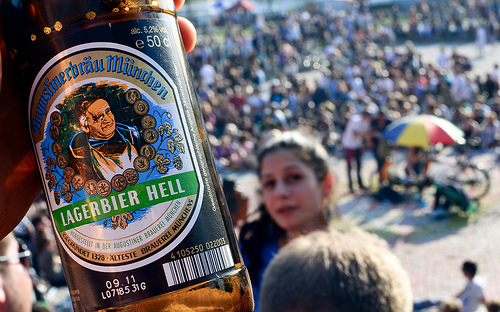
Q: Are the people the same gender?
A: No, they are both male and female.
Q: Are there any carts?
A: No, there are no carts.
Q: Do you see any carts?
A: No, there are no carts.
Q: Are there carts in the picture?
A: No, there are no carts.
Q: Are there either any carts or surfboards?
A: No, there are no carts or surfboards.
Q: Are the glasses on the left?
A: Yes, the glasses are on the left of the image.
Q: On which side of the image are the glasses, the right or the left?
A: The glasses are on the left of the image.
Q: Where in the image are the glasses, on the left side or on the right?
A: The glasses are on the left of the image.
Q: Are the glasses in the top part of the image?
A: No, the glasses are in the bottom of the image.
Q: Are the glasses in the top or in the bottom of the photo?
A: The glasses are in the bottom of the image.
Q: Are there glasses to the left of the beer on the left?
A: Yes, there are glasses to the left of the beer.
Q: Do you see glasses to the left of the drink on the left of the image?
A: Yes, there are glasses to the left of the beer.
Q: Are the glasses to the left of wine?
A: No, the glasses are to the left of the beer.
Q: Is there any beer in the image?
A: Yes, there is beer.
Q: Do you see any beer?
A: Yes, there is beer.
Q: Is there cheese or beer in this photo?
A: Yes, there is beer.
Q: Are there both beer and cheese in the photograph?
A: No, there is beer but no cheese.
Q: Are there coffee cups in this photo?
A: No, there are no coffee cups.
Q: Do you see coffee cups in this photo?
A: No, there are no coffee cups.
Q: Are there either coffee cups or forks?
A: No, there are no coffee cups or forks.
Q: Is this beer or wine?
A: This is beer.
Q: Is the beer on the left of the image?
A: Yes, the beer is on the left of the image.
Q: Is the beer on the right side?
A: No, the beer is on the left of the image.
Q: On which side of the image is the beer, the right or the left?
A: The beer is on the left of the image.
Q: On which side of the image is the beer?
A: The beer is on the left of the image.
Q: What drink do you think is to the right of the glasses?
A: The drink is beer.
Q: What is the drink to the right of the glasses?
A: The drink is beer.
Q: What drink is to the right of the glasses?
A: The drink is beer.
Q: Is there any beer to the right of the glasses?
A: Yes, there is beer to the right of the glasses.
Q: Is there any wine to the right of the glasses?
A: No, there is beer to the right of the glasses.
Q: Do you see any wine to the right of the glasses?
A: No, there is beer to the right of the glasses.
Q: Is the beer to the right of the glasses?
A: Yes, the beer is to the right of the glasses.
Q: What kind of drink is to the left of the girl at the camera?
A: The drink is beer.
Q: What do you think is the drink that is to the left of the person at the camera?
A: The drink is beer.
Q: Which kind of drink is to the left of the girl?
A: The drink is beer.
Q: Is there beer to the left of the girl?
A: Yes, there is beer to the left of the girl.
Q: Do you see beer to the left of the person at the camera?
A: Yes, there is beer to the left of the girl.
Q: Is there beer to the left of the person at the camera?
A: Yes, there is beer to the left of the girl.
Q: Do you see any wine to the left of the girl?
A: No, there is beer to the left of the girl.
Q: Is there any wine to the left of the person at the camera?
A: No, there is beer to the left of the girl.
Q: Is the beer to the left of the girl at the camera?
A: Yes, the beer is to the left of the girl.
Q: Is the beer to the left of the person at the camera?
A: Yes, the beer is to the left of the girl.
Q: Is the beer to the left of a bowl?
A: No, the beer is to the left of the girl.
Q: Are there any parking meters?
A: No, there are no parking meters.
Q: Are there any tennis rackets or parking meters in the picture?
A: No, there are no parking meters or tennis rackets.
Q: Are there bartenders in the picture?
A: No, there are no bartenders.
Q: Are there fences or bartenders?
A: No, there are no bartenders or fences.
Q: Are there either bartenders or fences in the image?
A: No, there are no bartenders or fences.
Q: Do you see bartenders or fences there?
A: No, there are no bartenders or fences.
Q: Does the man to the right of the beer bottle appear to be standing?
A: Yes, the man is standing.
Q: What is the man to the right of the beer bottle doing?
A: The man is standing.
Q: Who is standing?
A: The man is standing.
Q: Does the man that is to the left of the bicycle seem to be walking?
A: No, the man is standing.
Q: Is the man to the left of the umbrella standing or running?
A: The man is standing.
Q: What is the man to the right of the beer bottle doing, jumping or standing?
A: The man is standing.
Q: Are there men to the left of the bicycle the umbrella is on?
A: Yes, there is a man to the left of the bicycle.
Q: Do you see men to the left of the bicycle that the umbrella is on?
A: Yes, there is a man to the left of the bicycle.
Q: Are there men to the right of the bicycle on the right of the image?
A: No, the man is to the left of the bicycle.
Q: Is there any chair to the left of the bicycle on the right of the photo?
A: No, there is a man to the left of the bicycle.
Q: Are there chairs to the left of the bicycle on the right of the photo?
A: No, there is a man to the left of the bicycle.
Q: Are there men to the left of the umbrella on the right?
A: Yes, there is a man to the left of the umbrella.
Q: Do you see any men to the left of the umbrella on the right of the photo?
A: Yes, there is a man to the left of the umbrella.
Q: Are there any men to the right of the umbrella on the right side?
A: No, the man is to the left of the umbrella.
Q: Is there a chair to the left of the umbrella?
A: No, there is a man to the left of the umbrella.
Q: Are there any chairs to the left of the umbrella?
A: No, there is a man to the left of the umbrella.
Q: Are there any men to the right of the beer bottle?
A: Yes, there is a man to the right of the beer bottle.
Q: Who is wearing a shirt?
A: The man is wearing a shirt.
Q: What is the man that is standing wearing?
A: The man is wearing a shirt.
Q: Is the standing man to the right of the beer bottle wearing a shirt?
A: Yes, the man is wearing a shirt.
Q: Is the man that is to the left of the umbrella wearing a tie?
A: No, the man is wearing a shirt.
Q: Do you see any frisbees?
A: No, there are no frisbees.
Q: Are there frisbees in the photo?
A: No, there are no frisbees.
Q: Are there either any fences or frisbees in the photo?
A: No, there are no frisbees or fences.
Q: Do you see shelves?
A: No, there are no shelves.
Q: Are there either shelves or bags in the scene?
A: No, there are no shelves or bags.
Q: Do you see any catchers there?
A: No, there are no catchers.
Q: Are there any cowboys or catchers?
A: No, there are no catchers or cowboys.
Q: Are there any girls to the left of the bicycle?
A: Yes, there is a girl to the left of the bicycle.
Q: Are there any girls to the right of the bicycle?
A: No, the girl is to the left of the bicycle.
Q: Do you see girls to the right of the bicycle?
A: No, the girl is to the left of the bicycle.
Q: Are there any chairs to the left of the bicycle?
A: No, there is a girl to the left of the bicycle.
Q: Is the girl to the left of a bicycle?
A: Yes, the girl is to the left of a bicycle.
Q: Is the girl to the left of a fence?
A: No, the girl is to the left of a bicycle.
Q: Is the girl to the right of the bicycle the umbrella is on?
A: No, the girl is to the left of the bicycle.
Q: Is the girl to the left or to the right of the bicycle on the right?
A: The girl is to the left of the bicycle.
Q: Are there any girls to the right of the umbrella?
A: No, the girl is to the left of the umbrella.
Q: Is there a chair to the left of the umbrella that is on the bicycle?
A: No, there is a girl to the left of the umbrella.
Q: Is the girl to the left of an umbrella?
A: Yes, the girl is to the left of an umbrella.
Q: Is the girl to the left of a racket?
A: No, the girl is to the left of an umbrella.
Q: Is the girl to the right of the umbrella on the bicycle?
A: No, the girl is to the left of the umbrella.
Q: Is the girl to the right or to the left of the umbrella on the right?
A: The girl is to the left of the umbrella.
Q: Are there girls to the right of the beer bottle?
A: Yes, there is a girl to the right of the beer bottle.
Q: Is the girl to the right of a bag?
A: No, the girl is to the right of the beer bottle.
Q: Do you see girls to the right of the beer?
A: Yes, there is a girl to the right of the beer.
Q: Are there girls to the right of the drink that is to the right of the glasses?
A: Yes, there is a girl to the right of the beer.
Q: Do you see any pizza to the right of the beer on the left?
A: No, there is a girl to the right of the beer.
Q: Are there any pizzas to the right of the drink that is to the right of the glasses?
A: No, there is a girl to the right of the beer.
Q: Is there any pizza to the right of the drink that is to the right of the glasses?
A: No, there is a girl to the right of the beer.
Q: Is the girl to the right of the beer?
A: Yes, the girl is to the right of the beer.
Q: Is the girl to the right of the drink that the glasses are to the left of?
A: Yes, the girl is to the right of the beer.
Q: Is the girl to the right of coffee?
A: No, the girl is to the right of the beer.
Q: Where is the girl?
A: The girl is at the camera.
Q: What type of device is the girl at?
A: The girl is at the camera.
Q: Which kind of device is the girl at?
A: The girl is at the camera.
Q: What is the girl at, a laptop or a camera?
A: The girl is at a camera.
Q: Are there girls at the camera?
A: Yes, there is a girl at the camera.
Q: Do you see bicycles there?
A: Yes, there is a bicycle.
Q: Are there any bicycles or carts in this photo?
A: Yes, there is a bicycle.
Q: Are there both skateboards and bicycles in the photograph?
A: No, there is a bicycle but no skateboards.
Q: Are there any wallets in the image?
A: No, there are no wallets.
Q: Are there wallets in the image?
A: No, there are no wallets.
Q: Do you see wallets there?
A: No, there are no wallets.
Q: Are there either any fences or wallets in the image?
A: No, there are no wallets or fences.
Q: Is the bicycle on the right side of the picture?
A: Yes, the bicycle is on the right of the image.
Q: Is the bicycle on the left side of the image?
A: No, the bicycle is on the right of the image.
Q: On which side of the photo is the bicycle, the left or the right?
A: The bicycle is on the right of the image.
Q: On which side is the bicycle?
A: The bicycle is on the right of the image.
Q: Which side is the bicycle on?
A: The bicycle is on the right of the image.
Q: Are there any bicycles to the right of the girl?
A: Yes, there is a bicycle to the right of the girl.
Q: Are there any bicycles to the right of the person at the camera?
A: Yes, there is a bicycle to the right of the girl.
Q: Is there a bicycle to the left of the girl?
A: No, the bicycle is to the right of the girl.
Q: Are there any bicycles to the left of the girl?
A: No, the bicycle is to the right of the girl.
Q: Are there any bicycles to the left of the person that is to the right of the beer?
A: No, the bicycle is to the right of the girl.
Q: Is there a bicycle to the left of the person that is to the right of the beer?
A: No, the bicycle is to the right of the girl.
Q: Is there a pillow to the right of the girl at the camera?
A: No, there is a bicycle to the right of the girl.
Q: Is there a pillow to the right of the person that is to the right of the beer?
A: No, there is a bicycle to the right of the girl.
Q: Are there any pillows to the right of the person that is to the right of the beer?
A: No, there is a bicycle to the right of the girl.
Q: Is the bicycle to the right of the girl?
A: Yes, the bicycle is to the right of the girl.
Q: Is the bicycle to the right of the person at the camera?
A: Yes, the bicycle is to the right of the girl.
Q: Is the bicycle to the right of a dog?
A: No, the bicycle is to the right of the girl.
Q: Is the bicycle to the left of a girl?
A: No, the bicycle is to the right of a girl.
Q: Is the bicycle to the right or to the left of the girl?
A: The bicycle is to the right of the girl.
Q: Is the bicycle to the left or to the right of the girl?
A: The bicycle is to the right of the girl.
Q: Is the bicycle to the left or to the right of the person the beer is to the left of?
A: The bicycle is to the right of the girl.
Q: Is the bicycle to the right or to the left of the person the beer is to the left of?
A: The bicycle is to the right of the girl.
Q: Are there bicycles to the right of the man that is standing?
A: Yes, there is a bicycle to the right of the man.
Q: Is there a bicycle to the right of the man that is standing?
A: Yes, there is a bicycle to the right of the man.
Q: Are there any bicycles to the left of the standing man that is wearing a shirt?
A: No, the bicycle is to the right of the man.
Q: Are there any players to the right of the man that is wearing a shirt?
A: No, there is a bicycle to the right of the man.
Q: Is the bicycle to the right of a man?
A: Yes, the bicycle is to the right of a man.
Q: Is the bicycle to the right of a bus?
A: No, the bicycle is to the right of a man.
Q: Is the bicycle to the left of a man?
A: No, the bicycle is to the right of a man.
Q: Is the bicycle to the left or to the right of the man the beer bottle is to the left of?
A: The bicycle is to the right of the man.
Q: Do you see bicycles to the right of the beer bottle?
A: Yes, there is a bicycle to the right of the beer bottle.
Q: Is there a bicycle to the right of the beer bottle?
A: Yes, there is a bicycle to the right of the beer bottle.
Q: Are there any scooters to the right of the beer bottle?
A: No, there is a bicycle to the right of the beer bottle.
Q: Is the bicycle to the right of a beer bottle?
A: Yes, the bicycle is to the right of a beer bottle.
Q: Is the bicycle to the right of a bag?
A: No, the bicycle is to the right of a beer bottle.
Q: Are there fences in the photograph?
A: No, there are no fences.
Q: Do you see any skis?
A: No, there are no skis.